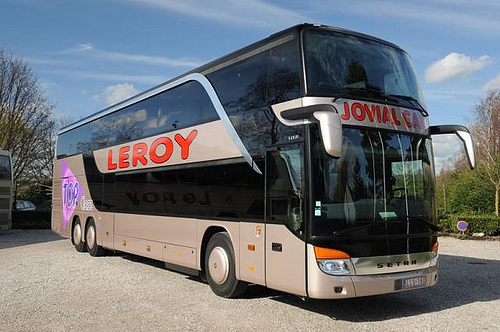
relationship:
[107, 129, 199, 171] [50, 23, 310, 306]
leroy on side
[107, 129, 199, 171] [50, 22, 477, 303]
leroy on bus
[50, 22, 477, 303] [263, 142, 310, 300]
bus has a door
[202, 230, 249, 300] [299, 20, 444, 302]
tire on front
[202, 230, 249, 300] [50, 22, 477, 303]
tire on bus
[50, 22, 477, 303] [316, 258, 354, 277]
bus has headlights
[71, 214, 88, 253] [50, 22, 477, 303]
tire on back of bus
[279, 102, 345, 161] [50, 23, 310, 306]
mirror on side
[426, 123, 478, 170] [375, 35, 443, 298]
mirror on drivers side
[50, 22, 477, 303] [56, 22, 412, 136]
bus has a roof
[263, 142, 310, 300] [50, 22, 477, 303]
door on bus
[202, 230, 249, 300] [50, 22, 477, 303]
tire on a bus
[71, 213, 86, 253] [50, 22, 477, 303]
tire on a bus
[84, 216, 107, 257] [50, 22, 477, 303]
tire on a bus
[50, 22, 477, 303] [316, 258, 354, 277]
bus has a headlight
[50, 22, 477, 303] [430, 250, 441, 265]
bus has a headlight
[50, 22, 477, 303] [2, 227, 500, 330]
bus in a parking lot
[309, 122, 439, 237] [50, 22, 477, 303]
windshield on bus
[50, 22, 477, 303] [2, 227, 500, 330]
bus on a lot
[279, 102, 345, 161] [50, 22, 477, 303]
mirror on bus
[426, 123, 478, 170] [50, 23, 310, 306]
mirror on side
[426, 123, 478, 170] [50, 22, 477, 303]
mirror on bus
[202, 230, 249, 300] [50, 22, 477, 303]
wheel on bus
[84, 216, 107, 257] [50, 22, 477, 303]
wheel on bus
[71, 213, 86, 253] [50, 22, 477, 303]
wheel on bus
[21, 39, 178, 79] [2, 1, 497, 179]
wispy clouds are in sky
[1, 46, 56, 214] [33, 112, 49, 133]
tree without leaves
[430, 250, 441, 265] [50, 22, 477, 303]
headlight on a bus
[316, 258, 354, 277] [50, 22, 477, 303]
headlight on a bus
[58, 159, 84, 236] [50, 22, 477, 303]
decal on bus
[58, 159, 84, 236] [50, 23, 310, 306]
decal on side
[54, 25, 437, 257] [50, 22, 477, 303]
windows on a bus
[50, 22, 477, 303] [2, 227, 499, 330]
bus on gravel